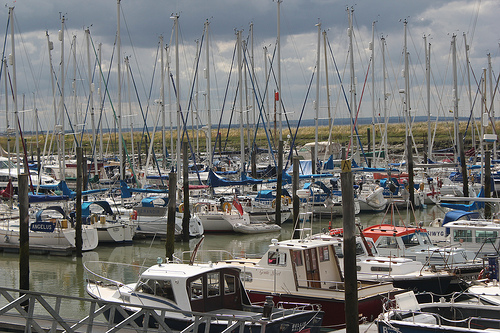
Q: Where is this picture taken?
A: A boat dock.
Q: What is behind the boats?
A: Grassy field.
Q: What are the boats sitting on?
A: Water.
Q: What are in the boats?
A: Metal poles.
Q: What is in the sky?
A: Clouds.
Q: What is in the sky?
A: Clouds.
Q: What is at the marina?
A: Yacht.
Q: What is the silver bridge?
A: Walkway.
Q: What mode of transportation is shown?
A: Boats.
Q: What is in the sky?
A: Clouds.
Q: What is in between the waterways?
A: Land.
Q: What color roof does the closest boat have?
A: White.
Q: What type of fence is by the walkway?
A: Wooden.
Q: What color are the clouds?
A: White.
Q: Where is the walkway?
A: Bottom left side of the image.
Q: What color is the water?
A: Gray.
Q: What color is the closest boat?
A: Black and white.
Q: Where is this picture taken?
A: A dock.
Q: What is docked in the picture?
A: Sailboats.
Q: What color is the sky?
A: Blue.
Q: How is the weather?
A: Clear.